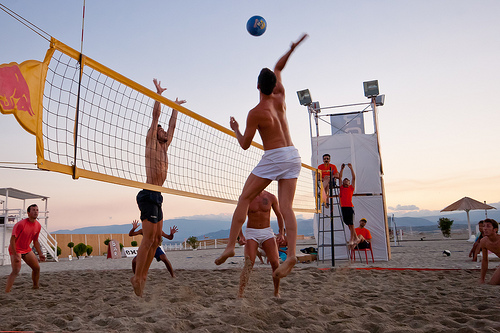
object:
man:
[213, 35, 311, 278]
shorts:
[251, 146, 304, 181]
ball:
[246, 15, 268, 37]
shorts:
[133, 186, 163, 223]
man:
[236, 188, 285, 298]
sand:
[1, 232, 498, 332]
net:
[1, 3, 329, 216]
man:
[337, 162, 359, 244]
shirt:
[338, 184, 355, 209]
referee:
[316, 153, 340, 206]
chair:
[316, 183, 350, 265]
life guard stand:
[1, 188, 61, 265]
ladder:
[36, 224, 58, 261]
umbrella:
[442, 197, 497, 240]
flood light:
[364, 80, 380, 96]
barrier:
[48, 233, 142, 259]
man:
[4, 205, 46, 290]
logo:
[149, 215, 157, 220]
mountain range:
[49, 206, 499, 241]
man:
[471, 220, 498, 286]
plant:
[67, 242, 74, 256]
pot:
[67, 254, 74, 260]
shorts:
[244, 226, 277, 244]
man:
[129, 79, 187, 298]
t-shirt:
[6, 219, 41, 252]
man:
[349, 218, 374, 251]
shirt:
[352, 227, 371, 239]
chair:
[349, 242, 376, 264]